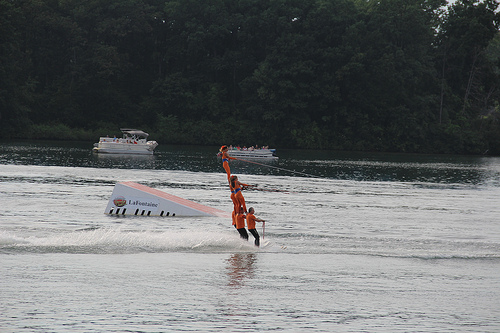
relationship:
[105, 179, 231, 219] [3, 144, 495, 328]
ramp on water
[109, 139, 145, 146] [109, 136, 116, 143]
bunch of person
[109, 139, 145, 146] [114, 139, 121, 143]
bunch of person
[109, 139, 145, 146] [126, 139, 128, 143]
bunch of person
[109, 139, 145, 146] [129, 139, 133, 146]
bunch of person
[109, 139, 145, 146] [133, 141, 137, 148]
bunch of person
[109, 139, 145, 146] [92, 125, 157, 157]
bunch on boat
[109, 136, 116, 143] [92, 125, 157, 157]
person on boat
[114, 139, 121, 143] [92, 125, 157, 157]
person on boat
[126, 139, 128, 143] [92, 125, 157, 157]
person on boat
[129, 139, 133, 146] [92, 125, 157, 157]
person on boat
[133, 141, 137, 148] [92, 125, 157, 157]
person on boat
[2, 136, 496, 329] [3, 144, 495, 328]
body of water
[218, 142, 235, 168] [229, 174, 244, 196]
person on top of person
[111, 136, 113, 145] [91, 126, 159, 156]
person on boat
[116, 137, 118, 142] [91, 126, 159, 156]
person on boat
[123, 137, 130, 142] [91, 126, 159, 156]
person on boat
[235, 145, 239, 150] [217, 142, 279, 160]
person on boat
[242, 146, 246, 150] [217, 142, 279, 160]
person on boat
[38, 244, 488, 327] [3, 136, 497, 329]
waters of lake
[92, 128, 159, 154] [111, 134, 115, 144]
boat with person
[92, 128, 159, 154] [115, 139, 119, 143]
boat with person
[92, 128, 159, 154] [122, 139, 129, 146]
boat with person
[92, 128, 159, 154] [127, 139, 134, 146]
boat with person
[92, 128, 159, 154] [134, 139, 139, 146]
boat with person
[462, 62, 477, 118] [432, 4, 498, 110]
trunk of tree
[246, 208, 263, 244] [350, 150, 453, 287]
man surfing on water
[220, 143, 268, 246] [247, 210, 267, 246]
group of person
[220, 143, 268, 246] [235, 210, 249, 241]
group of person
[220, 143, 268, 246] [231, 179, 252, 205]
group of person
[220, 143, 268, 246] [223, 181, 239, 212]
group of person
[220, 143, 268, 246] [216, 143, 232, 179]
group of person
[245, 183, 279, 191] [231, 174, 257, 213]
hand of person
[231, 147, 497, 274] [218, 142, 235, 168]
rope being pulled by person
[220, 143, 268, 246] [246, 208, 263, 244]
group of man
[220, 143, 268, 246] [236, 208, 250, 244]
group of man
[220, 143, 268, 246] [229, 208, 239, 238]
group of man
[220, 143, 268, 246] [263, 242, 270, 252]
group on ski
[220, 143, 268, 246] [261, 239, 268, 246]
group on ski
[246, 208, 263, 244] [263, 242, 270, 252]
man on ski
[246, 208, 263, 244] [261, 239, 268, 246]
man on ski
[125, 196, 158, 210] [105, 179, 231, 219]
word on side of ramp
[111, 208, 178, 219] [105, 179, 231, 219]
word on side of ramp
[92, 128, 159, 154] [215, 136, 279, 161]
boat in front of boat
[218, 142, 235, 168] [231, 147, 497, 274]
person pulling rope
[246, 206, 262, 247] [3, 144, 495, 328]
man wind surfing in water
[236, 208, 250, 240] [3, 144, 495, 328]
man wind surfing in water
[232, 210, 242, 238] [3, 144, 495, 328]
man wind surfing in water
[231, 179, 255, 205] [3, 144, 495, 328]
person wind surfing in water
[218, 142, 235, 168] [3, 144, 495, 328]
person wind surfing in water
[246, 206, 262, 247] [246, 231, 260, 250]
man in black pants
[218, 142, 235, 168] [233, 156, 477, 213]
person holding rope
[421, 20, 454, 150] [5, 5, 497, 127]
tree in woods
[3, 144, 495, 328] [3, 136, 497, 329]
water in lake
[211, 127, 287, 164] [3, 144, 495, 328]
boat on water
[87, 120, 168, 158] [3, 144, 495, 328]
boat on water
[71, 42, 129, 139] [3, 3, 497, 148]
tree in background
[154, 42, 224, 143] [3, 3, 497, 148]
tree in background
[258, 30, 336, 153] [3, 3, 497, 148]
tree in background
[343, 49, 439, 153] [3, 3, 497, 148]
tree in background